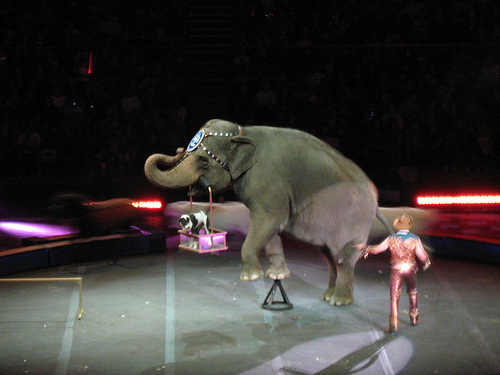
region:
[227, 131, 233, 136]
white spot on head harness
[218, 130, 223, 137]
white spot on head harness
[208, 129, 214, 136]
white spot on head harness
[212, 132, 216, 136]
white spot on head harness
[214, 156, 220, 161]
white spot on head harness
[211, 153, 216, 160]
white spot on head harness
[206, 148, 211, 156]
white spot on head harness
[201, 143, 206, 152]
white spot on head harness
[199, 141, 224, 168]
white spots on head harness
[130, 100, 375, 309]
grey circus elephant with front legs on stand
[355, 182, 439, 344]
elephant trainer in circus ring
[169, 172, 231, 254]
dog in basket carried by elephant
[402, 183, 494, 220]
runway lights for circus ring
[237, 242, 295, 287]
elephant feet on stand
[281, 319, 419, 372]
shadow of man walking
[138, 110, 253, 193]
head of circus elephant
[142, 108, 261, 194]
elephant wearing headress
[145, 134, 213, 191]
curled trunk of elephant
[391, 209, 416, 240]
broad-brimmed hat of circus performer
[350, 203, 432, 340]
circus ring leader in shiny pants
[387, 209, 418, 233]
light brown cow boy hat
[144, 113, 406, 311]
large grey circus elephant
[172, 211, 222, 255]
black and white spotted dog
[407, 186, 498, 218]
bright red row of lights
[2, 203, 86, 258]
bright purple light on the floor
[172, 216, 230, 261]
illuminated purple box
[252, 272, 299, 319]
black metal cone shaped stand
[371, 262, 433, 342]
shiny silver pants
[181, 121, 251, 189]
decorative head piece on an elephant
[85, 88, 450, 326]
a man and an elephant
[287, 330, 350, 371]
shadow of the man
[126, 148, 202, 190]
trunk of the elephant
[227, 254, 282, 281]
foot of the elephant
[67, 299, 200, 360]
lines on the ground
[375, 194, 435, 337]
back of the person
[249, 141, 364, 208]
the elephant is gray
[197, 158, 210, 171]
eye of the elephant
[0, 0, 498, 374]
A man in an animal show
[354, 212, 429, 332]
The person wearing a costume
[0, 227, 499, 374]
The rounded floor surface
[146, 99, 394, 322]
A gray jumbo in a show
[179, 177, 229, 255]
The hanging pink assortment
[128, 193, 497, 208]
The background brightly lit colors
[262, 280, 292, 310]
A dark stepping pointed platform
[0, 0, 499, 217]
The dark colosseum background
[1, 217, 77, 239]
The illuminated purple lighting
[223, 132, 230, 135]
white dot on headdress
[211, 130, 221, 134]
white dot on headdress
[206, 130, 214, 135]
white dot on headdress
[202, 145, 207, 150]
white dot on headdress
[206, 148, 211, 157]
white dot on headdress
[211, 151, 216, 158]
white dot on headdress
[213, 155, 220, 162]
white dot on headdress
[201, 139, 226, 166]
white dots on headdress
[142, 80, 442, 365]
an elephant in the circle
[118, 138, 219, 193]
an elephan with a trunk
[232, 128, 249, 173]
an elephant with ear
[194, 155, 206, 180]
an eye on the elephant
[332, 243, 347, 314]
a leg on the elephant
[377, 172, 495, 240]
a light on the stage